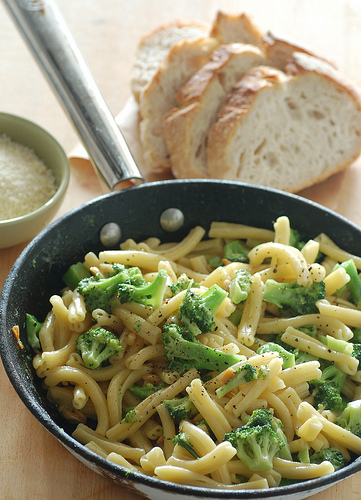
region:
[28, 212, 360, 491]
THE MACARONI IS YELLOW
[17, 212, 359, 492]
THE MACARONI IS MIXED WITH BROCCOLI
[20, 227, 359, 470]
THE BROCCOLI IS GREEN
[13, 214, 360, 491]
THE PEPPER IS ON THE BROCCOLI AND MACARONI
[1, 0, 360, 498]
THE MACARONI AND BROCCOLI IS IN THE PAN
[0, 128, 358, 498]
THE PAN IS ON THE COUNTER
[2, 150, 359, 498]
THE COUNTER IS WOODEN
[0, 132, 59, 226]
THE RICE IS WHITE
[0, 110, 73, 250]
THE RICE IS IN THE BOWL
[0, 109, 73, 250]
THE BOWL IS WHITE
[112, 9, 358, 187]
4 pieces of sliced bread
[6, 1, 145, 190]
silver handel of pan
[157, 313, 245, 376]
green piece of broccoli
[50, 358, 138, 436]
cooked pasta noodles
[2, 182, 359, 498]
pasta and broccoli dish in pan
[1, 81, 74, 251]
small bowl with white food item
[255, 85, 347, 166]
holes in a slice of bread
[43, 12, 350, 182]
slices of bread on a napkin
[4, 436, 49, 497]
wooden surface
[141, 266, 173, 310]
green stem on a piece of broccoli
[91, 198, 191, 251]
two round-headed silvertone bolts, maybe screws, fasten handle to pot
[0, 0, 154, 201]
handle is silvertone+shiny when clean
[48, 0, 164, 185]
a bar of reflected light down handle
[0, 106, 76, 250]
off-white/off-greygreen ramekin or its equivalent holds grated parmesan, or its equivalent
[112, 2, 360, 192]
four slices, minimum, of nicely crusted sourdough peasant bread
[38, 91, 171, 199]
napkin beneath bread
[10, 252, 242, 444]
several little garlic chips in pan, against side, atop noodle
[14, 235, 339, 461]
black pepper atop everything inside black pot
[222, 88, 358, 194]
some holes in the sourdough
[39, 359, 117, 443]
a double curl of double pasta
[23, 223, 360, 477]
the broccoli is green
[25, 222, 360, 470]
the broccoli is mixed with the mac-n-cheese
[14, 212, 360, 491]
the pepper is on the mac-n-cheese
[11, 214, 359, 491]
the mac-n-cheese is in the pan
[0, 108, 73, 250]
the rice is in the bowl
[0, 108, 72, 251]
the bowl is white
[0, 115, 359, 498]
the counter is wood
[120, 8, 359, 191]
the bred is behind the pan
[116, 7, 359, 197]
the bread is sliced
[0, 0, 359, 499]
the pan is on the counter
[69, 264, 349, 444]
Broccoli is green color.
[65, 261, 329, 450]
pasta is cream color.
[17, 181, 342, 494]
Pasta and broccoli in pan.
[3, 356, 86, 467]
Pan is black color.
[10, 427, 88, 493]
Table is brown color.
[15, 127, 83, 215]
Bowl is green color.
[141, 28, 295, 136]
Bread piece are besides the pan.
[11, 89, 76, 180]
Bowl is in table.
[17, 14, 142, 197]
Pan handle is silver color.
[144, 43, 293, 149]
Bread is brown color.